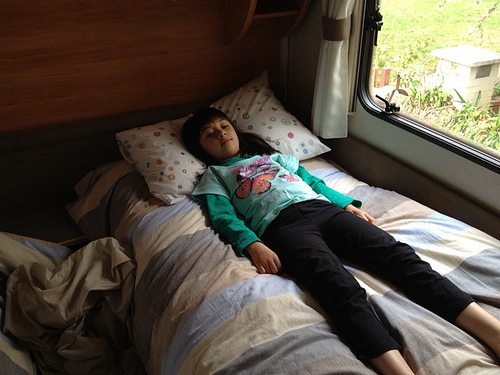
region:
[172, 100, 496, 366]
she is lying on a bed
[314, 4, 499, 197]
the window of a trailer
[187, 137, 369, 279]
she is wearing two shirts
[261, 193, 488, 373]
her pants are black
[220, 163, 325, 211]
her shirt has butterflies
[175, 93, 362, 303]
there are butterflies on her tee shirt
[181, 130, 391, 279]
her shirt is blue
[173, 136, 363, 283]
a short sleeve and a long sleeve shirt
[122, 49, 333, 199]
the pillow case is white and has spots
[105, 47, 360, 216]
the pillowcase is white and colorful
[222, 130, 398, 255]
this is a girl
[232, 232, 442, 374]
the pants are black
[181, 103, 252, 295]
this is a long sleeved shirt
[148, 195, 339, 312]
this is an arm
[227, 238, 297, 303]
this is a hand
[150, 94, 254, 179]
this is a head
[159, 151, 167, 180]
this is a pillow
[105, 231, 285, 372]
this is a bed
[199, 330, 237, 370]
the bed is striped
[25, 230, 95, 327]
this is a sheet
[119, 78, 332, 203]
circle pattern on the pillow case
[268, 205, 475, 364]
black pants on the little girl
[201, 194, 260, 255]
long sleeve is green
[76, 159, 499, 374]
the bed spread is striped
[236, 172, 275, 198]
a butterfly design on the shirt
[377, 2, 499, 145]
green plants are outside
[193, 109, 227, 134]
the young girl has bangs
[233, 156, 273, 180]
pink writing on the shirt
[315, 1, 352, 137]
white hanging curtains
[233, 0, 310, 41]
small wooden shelf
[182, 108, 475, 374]
The girl is lying on her bed.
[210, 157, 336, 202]
The girl has a green shirt with butterflies.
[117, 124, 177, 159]
Pillow on the bed.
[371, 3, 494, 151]
Window on the camper.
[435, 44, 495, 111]
A cement little wall.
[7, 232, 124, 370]
Blankets piled on the floor.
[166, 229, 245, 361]
Nice bedspread.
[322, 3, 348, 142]
Curtains at the window.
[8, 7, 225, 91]
Wood walls.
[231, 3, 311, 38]
Shelf on the wall.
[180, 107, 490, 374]
girl laying in bed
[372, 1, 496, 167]
window for looking outside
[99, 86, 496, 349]
girl is wearing black pants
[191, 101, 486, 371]
girl laying on a bed with strips on it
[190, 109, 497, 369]
girl wearing a green top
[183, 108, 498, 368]
girl wearing a green top with butterflys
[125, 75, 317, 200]
pillow with dots on it